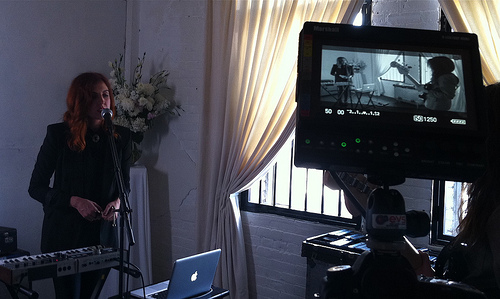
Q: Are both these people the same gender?
A: Yes, all the people are female.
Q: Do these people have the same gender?
A: Yes, all the people are female.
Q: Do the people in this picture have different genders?
A: No, all the people are female.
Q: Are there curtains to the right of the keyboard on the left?
A: Yes, there is a curtain to the right of the keyboard.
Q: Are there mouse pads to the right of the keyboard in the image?
A: No, there is a curtain to the right of the keyboard.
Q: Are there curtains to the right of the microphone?
A: Yes, there is a curtain to the right of the microphone.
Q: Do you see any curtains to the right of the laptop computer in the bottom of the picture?
A: Yes, there is a curtain to the right of the laptop computer.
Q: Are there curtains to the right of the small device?
A: Yes, there is a curtain to the right of the laptop computer.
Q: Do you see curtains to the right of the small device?
A: Yes, there is a curtain to the right of the laptop computer.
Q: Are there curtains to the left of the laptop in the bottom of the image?
A: No, the curtain is to the right of the laptop.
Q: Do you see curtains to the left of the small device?
A: No, the curtain is to the right of the laptop.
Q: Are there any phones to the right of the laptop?
A: No, there is a curtain to the right of the laptop.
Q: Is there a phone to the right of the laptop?
A: No, there is a curtain to the right of the laptop.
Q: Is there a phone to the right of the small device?
A: No, there is a curtain to the right of the laptop.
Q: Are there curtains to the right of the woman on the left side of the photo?
A: Yes, there is a curtain to the right of the woman.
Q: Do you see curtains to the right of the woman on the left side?
A: Yes, there is a curtain to the right of the woman.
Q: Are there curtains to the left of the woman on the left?
A: No, the curtain is to the right of the woman.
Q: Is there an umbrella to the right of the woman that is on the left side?
A: No, there is a curtain to the right of the woman.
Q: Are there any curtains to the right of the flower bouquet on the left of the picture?
A: Yes, there is a curtain to the right of the flower bouquet.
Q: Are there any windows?
A: Yes, there is a window.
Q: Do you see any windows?
A: Yes, there is a window.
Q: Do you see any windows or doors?
A: Yes, there is a window.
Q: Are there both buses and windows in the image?
A: No, there is a window but no buses.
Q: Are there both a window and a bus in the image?
A: No, there is a window but no buses.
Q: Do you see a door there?
A: No, there are no doors.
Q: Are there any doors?
A: No, there are no doors.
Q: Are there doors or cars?
A: No, there are no doors or cars.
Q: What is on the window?
A: The curtains are on the window.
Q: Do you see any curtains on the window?
A: Yes, there are curtains on the window.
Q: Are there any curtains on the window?
A: Yes, there are curtains on the window.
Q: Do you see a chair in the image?
A: No, there are no chairs.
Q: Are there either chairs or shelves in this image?
A: No, there are no chairs or shelves.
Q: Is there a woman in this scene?
A: Yes, there is a woman.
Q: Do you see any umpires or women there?
A: Yes, there is a woman.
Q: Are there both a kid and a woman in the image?
A: No, there is a woman but no children.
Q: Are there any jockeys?
A: No, there are no jockeys.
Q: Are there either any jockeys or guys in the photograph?
A: No, there are no jockeys or guys.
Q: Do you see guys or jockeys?
A: No, there are no jockeys or guys.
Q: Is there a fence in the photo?
A: No, there are no fences.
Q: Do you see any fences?
A: No, there are no fences.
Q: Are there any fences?
A: No, there are no fences.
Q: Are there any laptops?
A: Yes, there is a laptop.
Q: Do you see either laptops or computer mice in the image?
A: Yes, there is a laptop.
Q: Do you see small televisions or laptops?
A: Yes, there is a small laptop.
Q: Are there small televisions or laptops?
A: Yes, there is a small laptop.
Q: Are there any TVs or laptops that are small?
A: Yes, the laptop is small.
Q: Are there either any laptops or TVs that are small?
A: Yes, the laptop is small.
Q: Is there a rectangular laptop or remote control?
A: Yes, there is a rectangular laptop.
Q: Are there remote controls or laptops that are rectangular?
A: Yes, the laptop is rectangular.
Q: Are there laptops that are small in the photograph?
A: Yes, there is a small laptop.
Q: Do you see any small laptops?
A: Yes, there is a small laptop.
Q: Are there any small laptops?
A: Yes, there is a small laptop.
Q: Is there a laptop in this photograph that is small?
A: Yes, there is a laptop that is small.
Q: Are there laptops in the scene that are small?
A: Yes, there is a laptop that is small.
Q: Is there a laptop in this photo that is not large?
A: Yes, there is a small laptop.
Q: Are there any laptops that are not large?
A: Yes, there is a small laptop.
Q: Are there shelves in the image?
A: No, there are no shelves.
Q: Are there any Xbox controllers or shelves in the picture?
A: No, there are no shelves or Xbox controllers.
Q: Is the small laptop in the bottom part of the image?
A: Yes, the laptop is in the bottom of the image.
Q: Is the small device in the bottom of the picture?
A: Yes, the laptop is in the bottom of the image.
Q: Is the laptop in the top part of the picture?
A: No, the laptop is in the bottom of the image.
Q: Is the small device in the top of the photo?
A: No, the laptop is in the bottom of the image.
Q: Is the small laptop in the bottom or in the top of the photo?
A: The laptop computer is in the bottom of the image.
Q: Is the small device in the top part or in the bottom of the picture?
A: The laptop computer is in the bottom of the image.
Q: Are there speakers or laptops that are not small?
A: No, there is a laptop but it is small.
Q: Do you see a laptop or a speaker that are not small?
A: No, there is a laptop but it is small.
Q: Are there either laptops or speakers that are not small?
A: No, there is a laptop but it is small.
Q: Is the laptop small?
A: Yes, the laptop is small.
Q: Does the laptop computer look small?
A: Yes, the laptop computer is small.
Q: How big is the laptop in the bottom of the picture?
A: The laptop is small.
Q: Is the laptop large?
A: No, the laptop is small.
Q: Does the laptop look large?
A: No, the laptop is small.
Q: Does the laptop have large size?
A: No, the laptop is small.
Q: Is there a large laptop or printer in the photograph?
A: No, there is a laptop but it is small.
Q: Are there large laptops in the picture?
A: No, there is a laptop but it is small.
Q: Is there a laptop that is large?
A: No, there is a laptop but it is small.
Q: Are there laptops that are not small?
A: No, there is a laptop but it is small.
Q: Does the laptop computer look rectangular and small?
A: Yes, the laptop computer is rectangular and small.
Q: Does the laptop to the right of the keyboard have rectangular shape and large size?
A: No, the laptop is rectangular but small.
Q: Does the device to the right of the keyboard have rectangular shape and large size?
A: No, the laptop is rectangular but small.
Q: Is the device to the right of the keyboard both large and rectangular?
A: No, the laptop is rectangular but small.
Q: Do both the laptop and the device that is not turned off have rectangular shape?
A: Yes, both the laptop and the camera are rectangular.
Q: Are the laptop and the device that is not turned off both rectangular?
A: Yes, both the laptop and the camera are rectangular.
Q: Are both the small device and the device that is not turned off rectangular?
A: Yes, both the laptop and the camera are rectangular.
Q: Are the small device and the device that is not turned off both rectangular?
A: Yes, both the laptop and the camera are rectangular.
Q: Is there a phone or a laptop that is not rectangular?
A: No, there is a laptop but it is rectangular.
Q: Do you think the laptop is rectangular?
A: Yes, the laptop is rectangular.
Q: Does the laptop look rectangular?
A: Yes, the laptop is rectangular.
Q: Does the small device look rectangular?
A: Yes, the laptop is rectangular.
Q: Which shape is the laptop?
A: The laptop is rectangular.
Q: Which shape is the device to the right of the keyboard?
A: The laptop is rectangular.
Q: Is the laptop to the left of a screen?
A: No, the laptop is to the left of the curtain.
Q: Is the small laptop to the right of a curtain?
A: No, the laptop is to the left of a curtain.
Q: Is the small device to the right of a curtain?
A: No, the laptop is to the left of a curtain.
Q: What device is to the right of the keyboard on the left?
A: The device is a laptop.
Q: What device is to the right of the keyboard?
A: The device is a laptop.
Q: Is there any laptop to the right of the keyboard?
A: Yes, there is a laptop to the right of the keyboard.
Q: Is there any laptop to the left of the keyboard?
A: No, the laptop is to the right of the keyboard.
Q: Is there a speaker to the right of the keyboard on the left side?
A: No, there is a laptop to the right of the keyboard.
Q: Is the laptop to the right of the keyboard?
A: Yes, the laptop is to the right of the keyboard.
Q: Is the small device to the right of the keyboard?
A: Yes, the laptop is to the right of the keyboard.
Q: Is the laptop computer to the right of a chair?
A: No, the laptop computer is to the right of the keyboard.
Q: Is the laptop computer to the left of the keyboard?
A: No, the laptop computer is to the right of the keyboard.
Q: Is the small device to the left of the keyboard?
A: No, the laptop computer is to the right of the keyboard.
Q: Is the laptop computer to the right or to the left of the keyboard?
A: The laptop computer is to the right of the keyboard.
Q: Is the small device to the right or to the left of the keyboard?
A: The laptop computer is to the right of the keyboard.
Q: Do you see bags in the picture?
A: No, there are no bags.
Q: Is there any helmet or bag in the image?
A: No, there are no bags or helmets.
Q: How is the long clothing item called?
A: The clothing item is a jacket.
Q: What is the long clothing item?
A: The clothing item is a jacket.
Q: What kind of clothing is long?
A: The clothing is a jacket.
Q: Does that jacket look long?
A: Yes, the jacket is long.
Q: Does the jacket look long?
A: Yes, the jacket is long.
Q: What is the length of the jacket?
A: The jacket is long.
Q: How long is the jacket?
A: The jacket is long.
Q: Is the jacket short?
A: No, the jacket is long.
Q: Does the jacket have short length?
A: No, the jacket is long.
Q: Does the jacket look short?
A: No, the jacket is long.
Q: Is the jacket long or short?
A: The jacket is long.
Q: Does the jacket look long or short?
A: The jacket is long.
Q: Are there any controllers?
A: No, there are no controllers.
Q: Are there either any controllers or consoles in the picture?
A: No, there are no controllers or consoles.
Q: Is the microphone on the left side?
A: Yes, the microphone is on the left of the image.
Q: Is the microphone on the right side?
A: No, the microphone is on the left of the image.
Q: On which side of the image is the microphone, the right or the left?
A: The microphone is on the left of the image.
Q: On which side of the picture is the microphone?
A: The microphone is on the left of the image.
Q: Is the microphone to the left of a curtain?
A: Yes, the microphone is to the left of a curtain.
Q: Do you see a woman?
A: Yes, there is a woman.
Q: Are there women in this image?
A: Yes, there is a woman.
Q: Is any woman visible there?
A: Yes, there is a woman.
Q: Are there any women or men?
A: Yes, there is a woman.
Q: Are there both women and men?
A: No, there is a woman but no men.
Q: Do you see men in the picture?
A: No, there are no men.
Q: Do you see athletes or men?
A: No, there are no men or athletes.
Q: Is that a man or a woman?
A: That is a woman.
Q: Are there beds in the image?
A: No, there are no beds.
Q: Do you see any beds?
A: No, there are no beds.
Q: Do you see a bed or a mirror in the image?
A: No, there are no beds or mirrors.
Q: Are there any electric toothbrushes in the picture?
A: No, there are no electric toothbrushes.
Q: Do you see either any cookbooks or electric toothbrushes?
A: No, there are no electric toothbrushes or cookbooks.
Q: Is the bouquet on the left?
A: Yes, the bouquet is on the left of the image.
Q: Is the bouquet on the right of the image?
A: No, the bouquet is on the left of the image.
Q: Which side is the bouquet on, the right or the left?
A: The bouquet is on the left of the image.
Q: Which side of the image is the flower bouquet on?
A: The flower bouquet is on the left of the image.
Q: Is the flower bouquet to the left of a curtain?
A: Yes, the flower bouquet is to the left of a curtain.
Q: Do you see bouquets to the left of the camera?
A: Yes, there is a bouquet to the left of the camera.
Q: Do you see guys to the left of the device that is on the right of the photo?
A: No, there is a bouquet to the left of the camera.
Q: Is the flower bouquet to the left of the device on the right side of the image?
A: Yes, the flower bouquet is to the left of the camera.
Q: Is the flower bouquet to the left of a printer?
A: No, the flower bouquet is to the left of the camera.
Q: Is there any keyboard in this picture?
A: Yes, there is a keyboard.